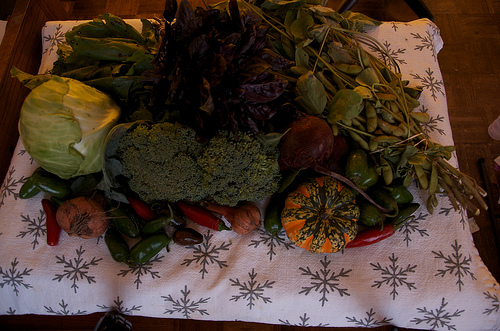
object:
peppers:
[343, 128, 370, 151]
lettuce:
[139, 0, 296, 141]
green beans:
[365, 100, 379, 133]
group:
[8, 0, 492, 266]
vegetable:
[8, 64, 124, 182]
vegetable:
[7, 39, 162, 103]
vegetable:
[279, 178, 363, 256]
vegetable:
[276, 113, 390, 214]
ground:
[0, 0, 500, 331]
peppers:
[142, 202, 175, 235]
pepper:
[127, 231, 174, 265]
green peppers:
[104, 226, 139, 268]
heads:
[143, 145, 144, 146]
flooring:
[0, 0, 500, 331]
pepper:
[350, 164, 386, 196]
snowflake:
[227, 266, 278, 311]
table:
[0, 0, 500, 331]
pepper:
[25, 174, 70, 196]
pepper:
[18, 165, 49, 201]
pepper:
[108, 206, 144, 238]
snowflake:
[14, 207, 50, 252]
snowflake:
[408, 295, 466, 330]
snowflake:
[431, 238, 479, 293]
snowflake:
[178, 228, 235, 281]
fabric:
[0, 13, 500, 331]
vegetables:
[54, 195, 110, 241]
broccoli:
[117, 121, 210, 206]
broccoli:
[201, 128, 284, 207]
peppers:
[40, 198, 61, 246]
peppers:
[125, 193, 157, 221]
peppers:
[176, 200, 233, 232]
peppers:
[344, 214, 417, 248]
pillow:
[0, 13, 500, 330]